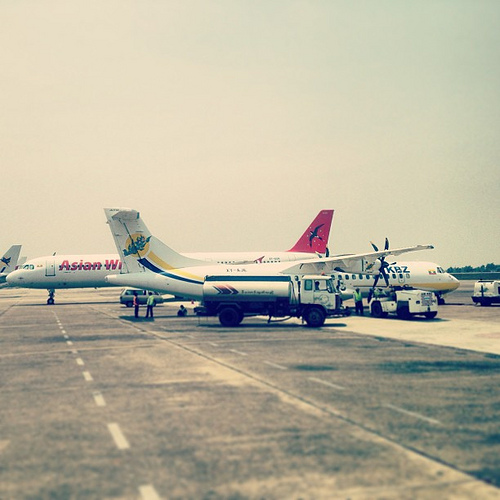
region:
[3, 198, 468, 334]
planes on a landing strip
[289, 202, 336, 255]
red stabilizers on a plane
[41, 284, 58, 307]
front wheel of plane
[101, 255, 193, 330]
people near planes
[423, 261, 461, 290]
the cockpit of a plane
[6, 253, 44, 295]
the cockpit of a plane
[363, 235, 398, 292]
a propeller on front a plane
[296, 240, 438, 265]
right wing of plane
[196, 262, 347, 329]
a truck in front a plane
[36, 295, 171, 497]
white lines on a landing strip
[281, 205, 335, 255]
pink tail fin of plane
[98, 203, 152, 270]
white tail fin of plane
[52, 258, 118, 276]
red writing on side of plane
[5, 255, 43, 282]
white cockpit of plane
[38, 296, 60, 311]
black front wheel of plane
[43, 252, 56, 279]
white door on side of plane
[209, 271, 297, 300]
fuel truck driving on street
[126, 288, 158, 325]
two mens tandign on tarmac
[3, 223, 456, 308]
two large planes parked on tarmac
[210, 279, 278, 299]
logo on side of plane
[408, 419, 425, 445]
part of a run way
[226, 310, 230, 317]
part of a wheel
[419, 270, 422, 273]
part of a plane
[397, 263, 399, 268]
edge of a plane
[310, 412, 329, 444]
part of a road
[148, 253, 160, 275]
side of a plane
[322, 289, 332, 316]
part of a truck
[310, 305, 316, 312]
part of a wheel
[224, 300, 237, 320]
edge of a wheel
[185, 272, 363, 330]
Gas truck fueling an airplane.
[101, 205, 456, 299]
A white airplane one yellow and one blue stripe.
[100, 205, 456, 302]
An airplane receiving fuel.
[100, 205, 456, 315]
An airplane on a runway.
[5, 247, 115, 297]
An airplane with red writing.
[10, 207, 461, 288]
Two airplanes on a runway.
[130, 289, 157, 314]
Two people standing below an airplane.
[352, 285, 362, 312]
A person standing beside an airplane.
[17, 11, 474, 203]
Clear skies above an airplane runway.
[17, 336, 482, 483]
An airplane runway on a clear day.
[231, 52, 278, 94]
this is the sky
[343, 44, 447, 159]
the sky is bright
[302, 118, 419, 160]
the sky is blue in color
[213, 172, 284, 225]
the sky has clouds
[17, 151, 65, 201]
the clouds are white in color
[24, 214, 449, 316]
these are some airplanes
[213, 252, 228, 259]
the airplane is white in color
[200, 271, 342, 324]
this is a fuel track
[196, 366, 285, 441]
this is the runway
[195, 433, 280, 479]
the runway is clean